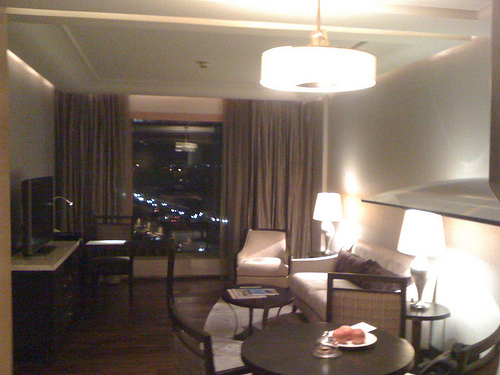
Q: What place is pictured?
A: It is a hotel room.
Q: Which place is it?
A: It is a hotel room.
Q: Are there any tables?
A: Yes, there is a table.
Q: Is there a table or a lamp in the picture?
A: Yes, there is a table.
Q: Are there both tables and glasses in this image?
A: No, there is a table but no glasses.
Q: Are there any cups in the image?
A: No, there are no cups.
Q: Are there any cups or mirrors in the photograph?
A: No, there are no cups or mirrors.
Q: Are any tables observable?
A: Yes, there is a table.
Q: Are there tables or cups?
A: Yes, there is a table.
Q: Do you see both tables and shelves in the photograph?
A: No, there is a table but no shelves.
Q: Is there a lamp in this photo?
A: Yes, there is a lamp.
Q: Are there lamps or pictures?
A: Yes, there is a lamp.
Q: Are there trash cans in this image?
A: No, there are no trash cans.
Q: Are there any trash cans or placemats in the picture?
A: No, there are no trash cans or placemats.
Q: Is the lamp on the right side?
A: Yes, the lamp is on the right of the image.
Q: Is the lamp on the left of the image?
A: No, the lamp is on the right of the image.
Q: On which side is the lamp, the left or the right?
A: The lamp is on the right of the image.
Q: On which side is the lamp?
A: The lamp is on the right of the image.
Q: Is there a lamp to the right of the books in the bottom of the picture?
A: Yes, there is a lamp to the right of the books.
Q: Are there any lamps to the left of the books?
A: No, the lamp is to the right of the books.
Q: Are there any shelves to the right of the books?
A: No, there is a lamp to the right of the books.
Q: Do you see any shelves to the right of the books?
A: No, there is a lamp to the right of the books.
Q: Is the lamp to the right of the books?
A: Yes, the lamp is to the right of the books.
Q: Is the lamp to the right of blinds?
A: No, the lamp is to the right of the books.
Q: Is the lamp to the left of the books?
A: No, the lamp is to the right of the books.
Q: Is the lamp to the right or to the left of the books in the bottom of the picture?
A: The lamp is to the right of the books.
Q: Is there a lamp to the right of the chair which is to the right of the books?
A: Yes, there is a lamp to the right of the chair.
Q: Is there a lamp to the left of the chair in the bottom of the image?
A: No, the lamp is to the right of the chair.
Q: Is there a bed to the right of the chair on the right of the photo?
A: No, there is a lamp to the right of the chair.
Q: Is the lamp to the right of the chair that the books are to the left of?
A: Yes, the lamp is to the right of the chair.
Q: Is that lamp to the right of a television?
A: No, the lamp is to the right of the chair.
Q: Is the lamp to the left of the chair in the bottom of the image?
A: No, the lamp is to the right of the chair.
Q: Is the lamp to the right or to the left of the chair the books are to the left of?
A: The lamp is to the right of the chair.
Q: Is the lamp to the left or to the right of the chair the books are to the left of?
A: The lamp is to the right of the chair.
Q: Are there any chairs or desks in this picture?
A: Yes, there is a chair.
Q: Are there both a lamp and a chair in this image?
A: Yes, there are both a chair and a lamp.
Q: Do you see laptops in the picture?
A: No, there are no laptops.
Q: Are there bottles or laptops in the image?
A: No, there are no laptops or bottles.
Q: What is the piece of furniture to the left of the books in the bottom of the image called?
A: The piece of furniture is a chair.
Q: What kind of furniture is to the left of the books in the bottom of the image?
A: The piece of furniture is a chair.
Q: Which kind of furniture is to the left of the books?
A: The piece of furniture is a chair.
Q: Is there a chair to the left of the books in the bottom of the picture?
A: Yes, there is a chair to the left of the books.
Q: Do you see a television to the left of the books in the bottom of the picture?
A: No, there is a chair to the left of the books.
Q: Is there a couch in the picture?
A: Yes, there is a couch.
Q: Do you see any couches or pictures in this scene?
A: Yes, there is a couch.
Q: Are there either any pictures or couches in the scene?
A: Yes, there is a couch.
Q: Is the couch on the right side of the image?
A: Yes, the couch is on the right of the image.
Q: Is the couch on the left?
A: No, the couch is on the right of the image.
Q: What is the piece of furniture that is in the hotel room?
A: The piece of furniture is a couch.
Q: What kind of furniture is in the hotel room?
A: The piece of furniture is a couch.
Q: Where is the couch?
A: The couch is in the hotel room.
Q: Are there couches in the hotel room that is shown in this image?
A: Yes, there is a couch in the hotel room.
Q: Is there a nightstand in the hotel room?
A: No, there is a couch in the hotel room.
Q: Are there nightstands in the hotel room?
A: No, there is a couch in the hotel room.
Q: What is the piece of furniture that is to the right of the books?
A: The piece of furniture is a couch.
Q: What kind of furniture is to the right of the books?
A: The piece of furniture is a couch.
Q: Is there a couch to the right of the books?
A: Yes, there is a couch to the right of the books.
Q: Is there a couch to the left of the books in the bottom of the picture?
A: No, the couch is to the right of the books.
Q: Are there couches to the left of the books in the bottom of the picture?
A: No, the couch is to the right of the books.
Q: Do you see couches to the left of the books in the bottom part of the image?
A: No, the couch is to the right of the books.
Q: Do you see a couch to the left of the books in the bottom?
A: No, the couch is to the right of the books.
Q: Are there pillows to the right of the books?
A: No, there is a couch to the right of the books.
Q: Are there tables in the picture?
A: Yes, there is a table.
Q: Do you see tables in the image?
A: Yes, there is a table.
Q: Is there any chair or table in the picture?
A: Yes, there is a table.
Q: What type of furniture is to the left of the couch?
A: The piece of furniture is a table.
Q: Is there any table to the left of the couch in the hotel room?
A: Yes, there is a table to the left of the couch.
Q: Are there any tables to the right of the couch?
A: No, the table is to the left of the couch.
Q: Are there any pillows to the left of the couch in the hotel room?
A: No, there is a table to the left of the couch.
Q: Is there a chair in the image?
A: Yes, there is a chair.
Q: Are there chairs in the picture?
A: Yes, there is a chair.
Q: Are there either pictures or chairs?
A: Yes, there is a chair.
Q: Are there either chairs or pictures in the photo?
A: Yes, there is a chair.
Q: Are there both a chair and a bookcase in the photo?
A: No, there is a chair but no bookcases.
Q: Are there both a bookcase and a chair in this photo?
A: No, there is a chair but no bookcases.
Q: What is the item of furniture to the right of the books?
A: The piece of furniture is a chair.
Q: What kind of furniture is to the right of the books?
A: The piece of furniture is a chair.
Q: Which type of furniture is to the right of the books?
A: The piece of furniture is a chair.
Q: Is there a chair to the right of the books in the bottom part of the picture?
A: Yes, there is a chair to the right of the books.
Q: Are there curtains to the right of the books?
A: No, there is a chair to the right of the books.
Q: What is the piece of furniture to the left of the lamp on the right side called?
A: The piece of furniture is a chair.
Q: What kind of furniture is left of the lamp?
A: The piece of furniture is a chair.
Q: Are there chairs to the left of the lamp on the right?
A: Yes, there is a chair to the left of the lamp.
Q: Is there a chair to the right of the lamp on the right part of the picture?
A: No, the chair is to the left of the lamp.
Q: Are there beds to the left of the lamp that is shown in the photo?
A: No, there is a chair to the left of the lamp.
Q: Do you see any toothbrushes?
A: No, there are no toothbrushes.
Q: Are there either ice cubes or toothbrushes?
A: No, there are no toothbrushes or ice cubes.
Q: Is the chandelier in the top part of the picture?
A: Yes, the chandelier is in the top of the image.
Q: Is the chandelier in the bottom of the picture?
A: No, the chandelier is in the top of the image.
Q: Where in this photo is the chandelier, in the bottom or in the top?
A: The chandelier is in the top of the image.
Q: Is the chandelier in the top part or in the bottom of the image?
A: The chandelier is in the top of the image.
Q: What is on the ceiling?
A: The chandelier is on the ceiling.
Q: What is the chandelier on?
A: The chandelier is on the ceiling.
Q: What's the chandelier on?
A: The chandelier is on the ceiling.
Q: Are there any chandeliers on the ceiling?
A: Yes, there is a chandelier on the ceiling.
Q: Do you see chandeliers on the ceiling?
A: Yes, there is a chandelier on the ceiling.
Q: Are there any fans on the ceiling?
A: No, there is a chandelier on the ceiling.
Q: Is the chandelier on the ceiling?
A: Yes, the chandelier is on the ceiling.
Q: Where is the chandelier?
A: The chandelier is in the hotel room.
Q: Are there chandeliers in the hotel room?
A: Yes, there is a chandelier in the hotel room.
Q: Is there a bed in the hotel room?
A: No, there is a chandelier in the hotel room.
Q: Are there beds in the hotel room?
A: No, there is a chandelier in the hotel room.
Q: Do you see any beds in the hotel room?
A: No, there is a chandelier in the hotel room.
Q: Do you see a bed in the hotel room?
A: No, there is a chandelier in the hotel room.